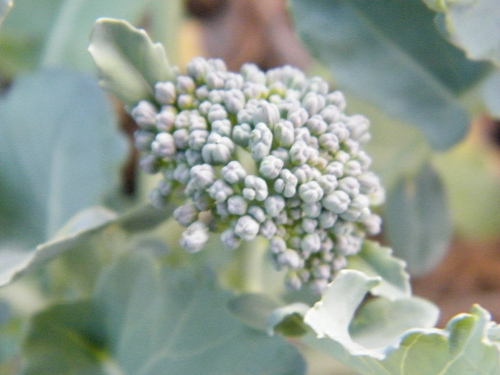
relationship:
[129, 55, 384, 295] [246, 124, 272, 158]
broccoli has a floret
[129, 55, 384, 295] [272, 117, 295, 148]
broccoli has florets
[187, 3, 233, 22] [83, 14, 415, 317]
person behind plant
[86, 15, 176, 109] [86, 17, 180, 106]
leaves look velvety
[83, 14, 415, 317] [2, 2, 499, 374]
plant are in photo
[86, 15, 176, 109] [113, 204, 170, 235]
leaves have shadows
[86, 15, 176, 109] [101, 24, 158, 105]
leaves have a line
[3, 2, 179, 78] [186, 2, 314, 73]
green in background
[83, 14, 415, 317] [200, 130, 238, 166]
plant has bud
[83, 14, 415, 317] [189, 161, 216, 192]
plant has bud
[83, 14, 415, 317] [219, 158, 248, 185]
plant has bud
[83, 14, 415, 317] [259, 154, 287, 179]
plant has bud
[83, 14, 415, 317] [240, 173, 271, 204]
plant has bud